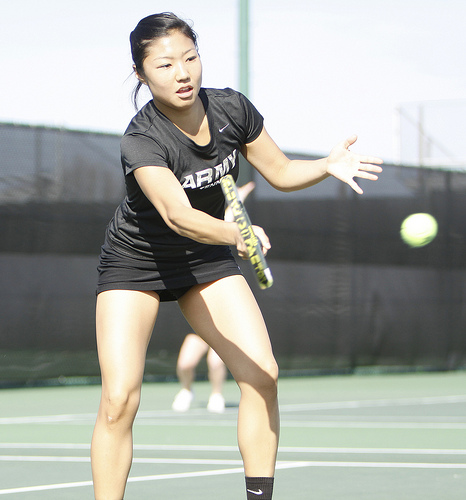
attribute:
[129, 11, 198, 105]
hair — dark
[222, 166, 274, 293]
racket — black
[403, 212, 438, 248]
ball — green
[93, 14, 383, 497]
woman — asian, standing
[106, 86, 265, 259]
shirt — black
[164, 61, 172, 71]
eye — brown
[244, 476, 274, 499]
sock — black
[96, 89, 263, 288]
uniform — black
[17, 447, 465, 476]
line — white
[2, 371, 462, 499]
tennis court — green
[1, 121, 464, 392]
screen — black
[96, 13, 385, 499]
player — female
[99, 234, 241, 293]
skirt — black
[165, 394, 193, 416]
shoes — white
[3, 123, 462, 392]
fence — black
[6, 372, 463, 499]
court — white